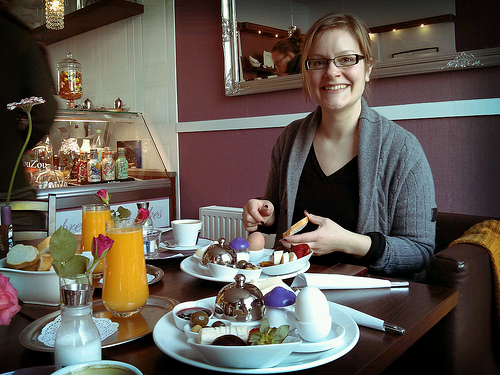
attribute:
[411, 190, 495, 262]
chair — brown, leather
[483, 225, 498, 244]
material — yellow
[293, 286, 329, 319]
egg — brown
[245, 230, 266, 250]
egg — brown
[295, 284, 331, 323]
egg — white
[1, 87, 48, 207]
flower — purple, tall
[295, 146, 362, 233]
shirt — black